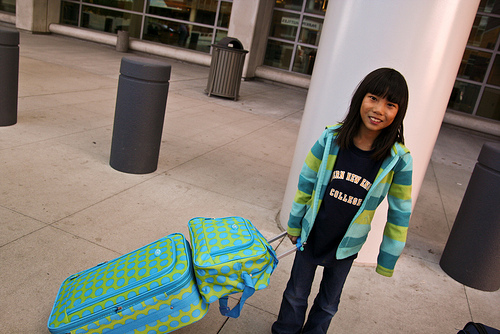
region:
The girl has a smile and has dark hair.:
[332, 67, 408, 159]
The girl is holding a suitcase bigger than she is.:
[48, 65, 413, 332]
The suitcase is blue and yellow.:
[46, 215, 302, 330]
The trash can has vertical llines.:
[205, 36, 247, 100]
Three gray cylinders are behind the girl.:
[0, 23, 499, 290]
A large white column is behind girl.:
[283, 0, 481, 257]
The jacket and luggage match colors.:
[45, 125, 420, 330]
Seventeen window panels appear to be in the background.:
[0, 0, 499, 126]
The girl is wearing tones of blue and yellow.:
[271, 66, 414, 331]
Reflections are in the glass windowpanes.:
[56, 1, 498, 129]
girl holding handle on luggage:
[265, 210, 348, 276]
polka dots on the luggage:
[113, 252, 150, 294]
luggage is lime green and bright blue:
[115, 262, 180, 307]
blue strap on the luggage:
[213, 287, 253, 313]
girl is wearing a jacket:
[297, 169, 338, 219]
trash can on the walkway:
[200, 40, 259, 101]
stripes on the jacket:
[306, 168, 314, 228]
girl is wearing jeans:
[290, 280, 310, 315]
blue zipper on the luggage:
[139, 292, 157, 300]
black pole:
[101, 59, 160, 165]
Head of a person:
[342, 45, 419, 150]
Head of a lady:
[355, 64, 420, 148]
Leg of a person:
[309, 253, 363, 332]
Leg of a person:
[272, 246, 320, 328]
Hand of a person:
[377, 153, 420, 285]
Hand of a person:
[277, 122, 332, 246]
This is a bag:
[184, 215, 283, 308]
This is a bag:
[46, 227, 193, 332]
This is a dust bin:
[108, 40, 174, 187]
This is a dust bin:
[202, 34, 255, 113]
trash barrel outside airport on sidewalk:
[200, 32, 251, 104]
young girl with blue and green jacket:
[274, 66, 417, 321]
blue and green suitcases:
[39, 212, 303, 324]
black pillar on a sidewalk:
[97, 50, 174, 175]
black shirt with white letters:
[310, 157, 382, 254]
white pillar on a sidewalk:
[285, 2, 477, 254]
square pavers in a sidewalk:
[1, 139, 167, 238]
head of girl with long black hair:
[335, 61, 410, 152]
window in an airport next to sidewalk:
[264, 0, 332, 82]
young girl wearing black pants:
[268, 228, 358, 329]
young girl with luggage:
[35, 65, 417, 325]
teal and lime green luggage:
[49, 213, 282, 333]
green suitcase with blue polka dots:
[49, 219, 272, 331]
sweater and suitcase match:
[45, 142, 414, 331]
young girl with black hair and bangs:
[337, 63, 412, 167]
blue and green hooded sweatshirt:
[289, 127, 407, 277]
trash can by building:
[205, 27, 250, 103]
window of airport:
[150, 4, 320, 65]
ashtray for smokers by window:
[111, 24, 132, 56]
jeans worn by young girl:
[278, 232, 356, 332]